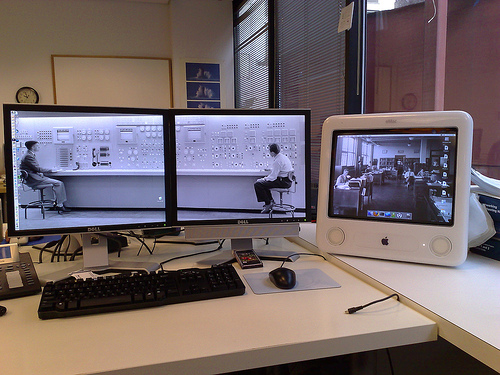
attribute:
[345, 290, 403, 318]
cord — black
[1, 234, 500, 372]
desk — white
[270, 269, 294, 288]
mouse — black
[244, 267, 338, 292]
pad — gray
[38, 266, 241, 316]
keyboard — black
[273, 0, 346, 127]
blinds — open, white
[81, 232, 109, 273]
base on computer — silver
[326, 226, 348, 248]
knob on screen — white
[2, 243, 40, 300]
telephone — gray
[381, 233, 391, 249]
logo — black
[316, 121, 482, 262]
apple monitor — white, on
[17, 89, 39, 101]
clock — black, white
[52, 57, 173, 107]
board — white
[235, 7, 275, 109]
blinds — white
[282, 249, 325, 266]
cord — black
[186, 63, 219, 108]
poster — blue, white